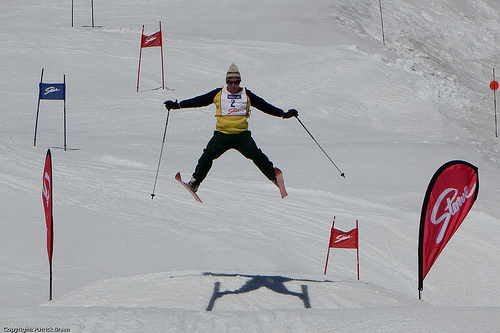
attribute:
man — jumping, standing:
[161, 53, 304, 208]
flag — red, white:
[134, 21, 172, 53]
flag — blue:
[36, 76, 72, 105]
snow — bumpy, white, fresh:
[341, 3, 495, 120]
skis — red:
[172, 164, 296, 207]